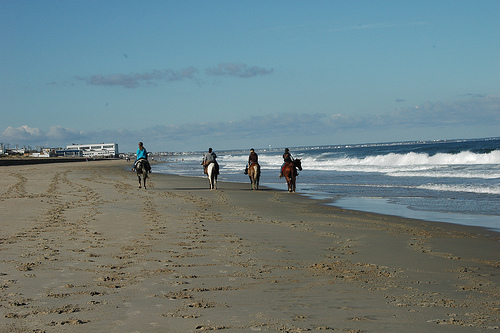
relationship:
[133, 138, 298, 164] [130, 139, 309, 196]
people riding horses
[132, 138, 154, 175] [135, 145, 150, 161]
rider wears jacket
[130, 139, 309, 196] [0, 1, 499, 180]
horses face away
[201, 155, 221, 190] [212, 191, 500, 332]
horse leaves hoofprints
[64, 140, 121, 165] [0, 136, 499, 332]
building on beach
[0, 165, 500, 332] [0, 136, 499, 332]
footprints in sand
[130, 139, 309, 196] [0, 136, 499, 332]
horses on beach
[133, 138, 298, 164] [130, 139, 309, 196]
riders on horses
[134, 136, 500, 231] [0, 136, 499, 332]
surf on beach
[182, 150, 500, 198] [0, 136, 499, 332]
waves on beach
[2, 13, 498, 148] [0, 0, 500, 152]
clouds in sky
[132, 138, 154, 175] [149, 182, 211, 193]
rider has shadow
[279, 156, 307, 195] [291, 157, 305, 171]
horse has head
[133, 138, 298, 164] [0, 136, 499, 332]
people on beach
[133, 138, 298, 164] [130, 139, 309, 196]
people on horses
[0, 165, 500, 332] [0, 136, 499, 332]
footprints on sand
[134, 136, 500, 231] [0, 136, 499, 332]
water by beach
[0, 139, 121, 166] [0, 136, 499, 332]
buildings on beach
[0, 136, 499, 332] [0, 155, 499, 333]
sand on beach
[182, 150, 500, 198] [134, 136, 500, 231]
waves in water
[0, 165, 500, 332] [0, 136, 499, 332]
tracks in sand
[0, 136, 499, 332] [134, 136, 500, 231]
sand near water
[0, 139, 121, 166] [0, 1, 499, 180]
buildings in distance